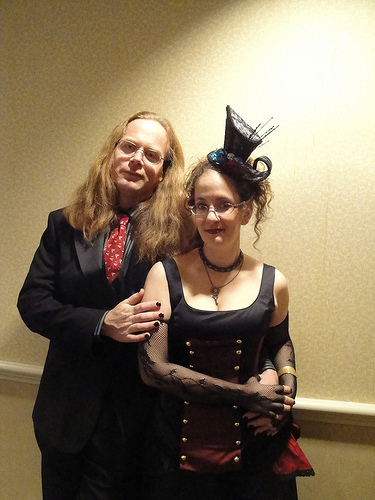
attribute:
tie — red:
[103, 219, 126, 280]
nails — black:
[154, 303, 164, 307]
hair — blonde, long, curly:
[64, 110, 201, 263]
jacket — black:
[15, 203, 178, 457]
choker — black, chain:
[198, 245, 244, 273]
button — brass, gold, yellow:
[235, 337, 243, 347]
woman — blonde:
[137, 161, 314, 499]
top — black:
[160, 256, 315, 480]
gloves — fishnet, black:
[137, 321, 283, 419]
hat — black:
[208, 108, 272, 183]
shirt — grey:
[104, 208, 152, 292]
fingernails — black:
[157, 313, 167, 319]